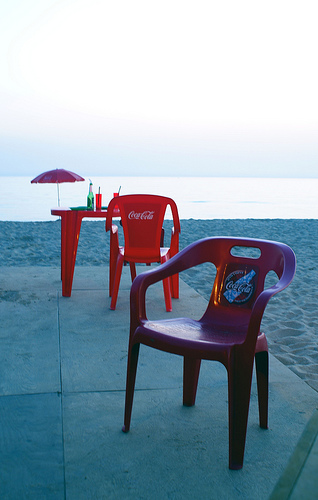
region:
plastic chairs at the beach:
[5, 4, 312, 493]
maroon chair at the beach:
[117, 233, 300, 473]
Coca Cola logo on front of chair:
[216, 258, 262, 313]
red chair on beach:
[101, 191, 184, 314]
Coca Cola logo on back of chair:
[125, 207, 155, 222]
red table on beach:
[49, 205, 138, 301]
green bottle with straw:
[86, 176, 95, 210]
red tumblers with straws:
[94, 183, 123, 212]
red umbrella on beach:
[29, 165, 86, 220]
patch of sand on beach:
[280, 295, 314, 356]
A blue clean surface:
[72, 439, 216, 485]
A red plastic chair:
[119, 235, 299, 477]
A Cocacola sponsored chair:
[126, 202, 159, 226]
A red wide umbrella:
[26, 165, 85, 189]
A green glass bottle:
[86, 180, 95, 213]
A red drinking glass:
[95, 191, 103, 209]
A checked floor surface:
[22, 312, 91, 436]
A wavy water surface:
[287, 225, 314, 241]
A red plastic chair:
[49, 205, 83, 299]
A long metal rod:
[56, 181, 61, 208]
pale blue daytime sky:
[6, 123, 312, 174]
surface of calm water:
[0, 179, 314, 220]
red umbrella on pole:
[33, 168, 83, 208]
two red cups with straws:
[94, 185, 123, 209]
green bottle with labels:
[86, 183, 95, 210]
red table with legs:
[53, 205, 122, 297]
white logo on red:
[122, 207, 156, 226]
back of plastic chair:
[103, 194, 181, 312]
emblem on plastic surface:
[217, 261, 258, 308]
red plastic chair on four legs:
[122, 235, 294, 468]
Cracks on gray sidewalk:
[52, 299, 69, 497]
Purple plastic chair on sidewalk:
[122, 235, 296, 463]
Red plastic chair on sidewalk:
[104, 194, 181, 310]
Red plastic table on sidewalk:
[48, 205, 161, 295]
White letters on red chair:
[126, 208, 155, 222]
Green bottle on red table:
[87, 182, 93, 208]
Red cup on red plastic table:
[94, 194, 102, 208]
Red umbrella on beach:
[31, 168, 84, 182]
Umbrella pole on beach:
[57, 182, 62, 221]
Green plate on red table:
[69, 205, 89, 209]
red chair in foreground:
[121, 232, 292, 455]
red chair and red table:
[40, 191, 183, 312]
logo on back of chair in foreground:
[212, 264, 257, 308]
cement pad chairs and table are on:
[6, 260, 313, 499]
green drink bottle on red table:
[87, 180, 93, 209]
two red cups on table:
[93, 184, 122, 211]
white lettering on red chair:
[123, 207, 159, 225]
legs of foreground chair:
[106, 350, 273, 460]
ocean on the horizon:
[4, 171, 313, 217]